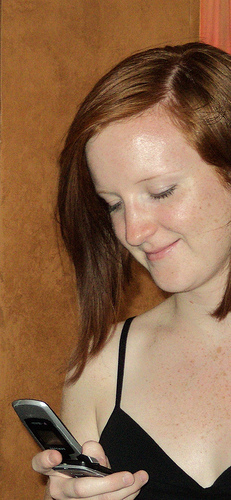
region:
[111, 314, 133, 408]
one black camisole strap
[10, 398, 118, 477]
one black and silver flip style phone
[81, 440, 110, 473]
one thumb curved over phone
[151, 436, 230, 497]
black V neck of woman's shirt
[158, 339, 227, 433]
bunch of freckles on Caucasian skin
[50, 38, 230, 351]
one woman with medium length red hair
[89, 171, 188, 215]
woman with thin red eyebrows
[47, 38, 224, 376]
woman with straight red hair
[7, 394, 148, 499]
one hand holding cell phone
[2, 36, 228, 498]
A woman in the foreground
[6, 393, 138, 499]
Cell phone is sliver in color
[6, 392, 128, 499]
Cell phone is a flip phone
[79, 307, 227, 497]
Woman is wearing a black dress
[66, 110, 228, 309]
Woman is looking down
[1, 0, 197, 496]
Background wall is brown in color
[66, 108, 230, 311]
Woman in the foreground is smiling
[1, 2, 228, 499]
Photo was taken indoors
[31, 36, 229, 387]
Woman has long hair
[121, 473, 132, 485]
she has no finger nail polish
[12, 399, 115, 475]
a silver and black flip phone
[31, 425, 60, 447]
the front of the phone has a screen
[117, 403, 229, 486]
a V neck shirt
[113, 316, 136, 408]
a black tank top strap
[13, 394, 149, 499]
she is holding the phone is her right hand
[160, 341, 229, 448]
freckles on her chest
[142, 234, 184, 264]
the girl is smiling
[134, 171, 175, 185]
her eyebrows are thin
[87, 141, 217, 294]
face of the woman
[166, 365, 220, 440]
freckles on the skin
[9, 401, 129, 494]
phone in the hand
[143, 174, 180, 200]
eye of the woman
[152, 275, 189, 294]
chin of the woman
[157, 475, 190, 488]
the shirt is black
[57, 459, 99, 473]
back of the phone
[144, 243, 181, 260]
woman's think pink lips.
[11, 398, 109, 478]
Hands holding old flip phone.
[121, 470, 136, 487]
Short fingernails on woman's fingers.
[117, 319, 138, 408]
Black sphaghetti strap top.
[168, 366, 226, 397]
Freckles on girl's chest.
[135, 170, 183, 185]
Reddish brown thin eyebrows.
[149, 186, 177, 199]
Girl's long dark eyelashes.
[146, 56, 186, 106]
Girl with a side part in hair.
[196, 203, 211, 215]
Girl with beauty mark on face.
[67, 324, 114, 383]
Hair gently touching shoulder.